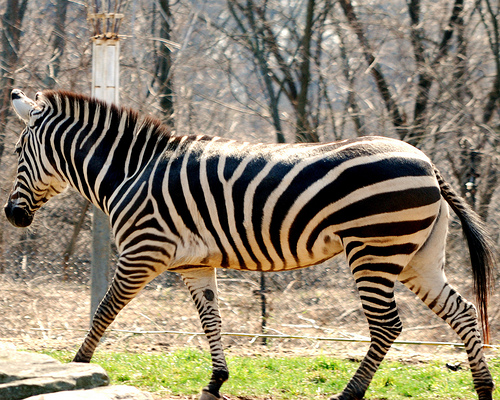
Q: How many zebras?
A: 1.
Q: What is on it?
A: Strips.